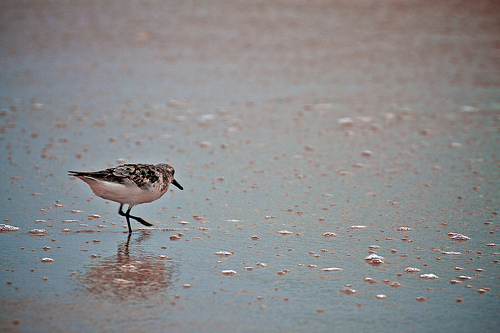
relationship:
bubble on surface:
[335, 104, 364, 141] [229, 67, 465, 286]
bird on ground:
[68, 120, 198, 265] [27, 98, 329, 333]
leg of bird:
[118, 217, 141, 236] [68, 120, 198, 265]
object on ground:
[362, 224, 400, 278] [27, 98, 329, 333]